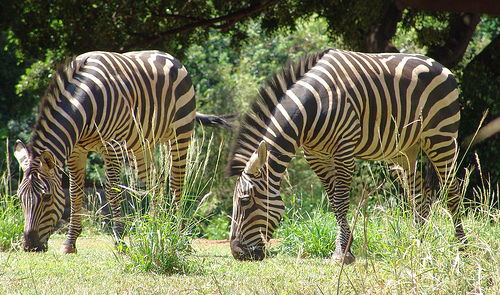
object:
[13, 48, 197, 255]
zebra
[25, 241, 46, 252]
mouth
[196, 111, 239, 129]
tail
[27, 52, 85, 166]
mane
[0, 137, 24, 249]
grass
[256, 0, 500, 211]
tree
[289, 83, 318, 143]
stripe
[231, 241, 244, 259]
nose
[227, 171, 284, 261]
head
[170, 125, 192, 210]
leg